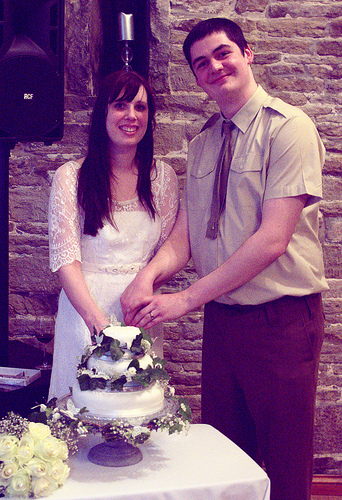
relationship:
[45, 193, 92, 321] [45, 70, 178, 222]
arm on woman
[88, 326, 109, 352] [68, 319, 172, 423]
flower decorating cake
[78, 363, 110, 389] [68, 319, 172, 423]
flower decorating cake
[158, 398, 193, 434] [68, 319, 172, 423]
flower decorating cake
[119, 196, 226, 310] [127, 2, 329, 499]
arm of a man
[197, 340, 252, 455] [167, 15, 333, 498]
leg of a man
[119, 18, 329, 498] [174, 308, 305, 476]
guy wearing pants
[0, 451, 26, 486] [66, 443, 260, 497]
rose on table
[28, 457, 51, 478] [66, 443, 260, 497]
rose on table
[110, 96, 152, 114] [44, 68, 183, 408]
eyes of woman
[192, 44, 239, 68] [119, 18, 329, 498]
eyes of guy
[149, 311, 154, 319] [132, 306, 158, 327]
ring on finger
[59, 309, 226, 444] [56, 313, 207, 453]
butterflies on cake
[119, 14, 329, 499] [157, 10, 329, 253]
guy has head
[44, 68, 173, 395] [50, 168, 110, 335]
woman has arm